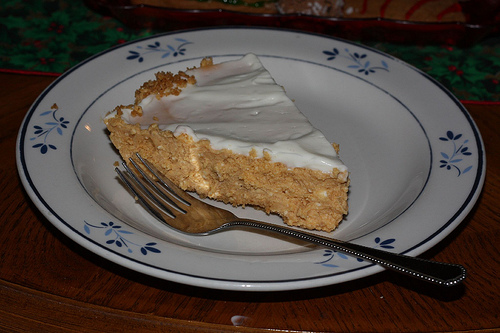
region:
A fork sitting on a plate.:
[110, 148, 470, 292]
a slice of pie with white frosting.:
[124, 52, 349, 190]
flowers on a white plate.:
[74, 202, 167, 272]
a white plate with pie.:
[19, 25, 493, 302]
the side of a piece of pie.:
[101, 117, 349, 236]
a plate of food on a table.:
[13, 15, 498, 301]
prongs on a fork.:
[102, 145, 190, 225]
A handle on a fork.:
[244, 214, 468, 289]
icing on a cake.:
[93, 52, 354, 182]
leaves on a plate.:
[136, 230, 170, 262]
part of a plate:
[466, 133, 473, 146]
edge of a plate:
[315, 282, 316, 289]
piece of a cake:
[259, 187, 271, 217]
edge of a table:
[178, 310, 181, 321]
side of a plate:
[379, 170, 387, 181]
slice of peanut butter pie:
[97, 47, 359, 245]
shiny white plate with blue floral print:
[14, 22, 494, 295]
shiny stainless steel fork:
[111, 145, 474, 300]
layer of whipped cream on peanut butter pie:
[106, 50, 356, 181]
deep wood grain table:
[0, 65, 496, 330]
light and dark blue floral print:
[71, 208, 166, 267]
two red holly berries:
[447, 62, 467, 77]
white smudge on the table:
[225, 307, 250, 330]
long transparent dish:
[86, 2, 488, 35]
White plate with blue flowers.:
[402, 107, 472, 234]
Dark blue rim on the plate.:
[434, 107, 484, 256]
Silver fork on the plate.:
[100, 160, 470, 249]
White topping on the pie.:
[117, 28, 349, 173]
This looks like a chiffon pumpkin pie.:
[90, 110, 362, 199]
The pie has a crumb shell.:
[114, 47, 230, 109]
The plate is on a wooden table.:
[2, 56, 105, 243]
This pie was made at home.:
[111, 36, 373, 225]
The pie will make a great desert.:
[104, 33, 379, 211]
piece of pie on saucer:
[16, 42, 461, 266]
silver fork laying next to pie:
[107, 136, 496, 286]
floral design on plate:
[28, 215, 226, 311]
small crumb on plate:
[103, 141, 129, 173]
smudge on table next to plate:
[198, 299, 277, 331]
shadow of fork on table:
[363, 247, 480, 309]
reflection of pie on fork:
[100, 157, 240, 247]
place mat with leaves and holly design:
[356, 28, 496, 99]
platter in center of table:
[32, 0, 489, 55]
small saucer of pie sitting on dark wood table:
[8, 1, 475, 331]